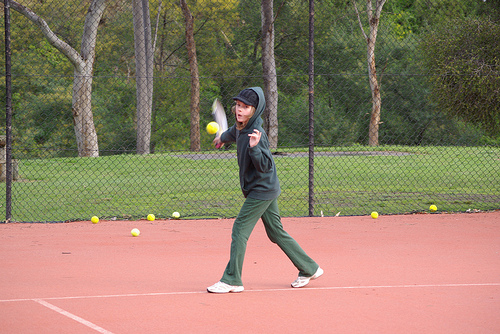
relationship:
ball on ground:
[369, 210, 381, 222] [3, 203, 500, 332]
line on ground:
[35, 296, 115, 330] [3, 203, 500, 332]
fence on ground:
[4, 4, 499, 222] [3, 203, 500, 332]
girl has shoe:
[207, 86, 325, 295] [204, 277, 243, 294]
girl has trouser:
[207, 86, 325, 295] [222, 201, 320, 286]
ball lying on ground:
[369, 210, 381, 222] [3, 203, 500, 332]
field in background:
[4, 147, 499, 224] [2, 9, 500, 215]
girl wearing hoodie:
[207, 86, 325, 295] [219, 84, 283, 199]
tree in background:
[1, 6, 115, 163] [2, 9, 500, 215]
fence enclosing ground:
[4, 4, 499, 222] [3, 203, 500, 332]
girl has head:
[207, 86, 325, 295] [230, 87, 265, 124]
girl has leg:
[207, 86, 325, 295] [221, 194, 273, 292]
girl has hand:
[207, 86, 325, 295] [247, 130, 265, 152]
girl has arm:
[207, 86, 325, 295] [251, 120, 274, 176]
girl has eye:
[207, 86, 325, 295] [235, 100, 244, 107]